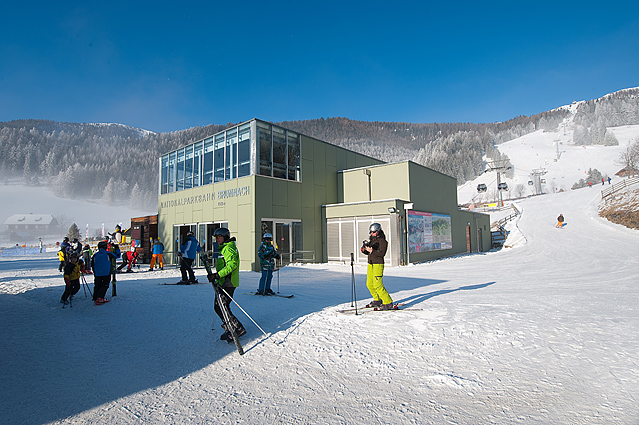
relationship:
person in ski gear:
[355, 214, 408, 260] [360, 235, 404, 314]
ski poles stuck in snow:
[343, 252, 366, 317] [308, 293, 468, 369]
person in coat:
[197, 207, 245, 272] [215, 242, 242, 302]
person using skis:
[250, 224, 280, 275] [243, 279, 308, 309]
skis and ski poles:
[243, 279, 308, 309] [274, 252, 301, 312]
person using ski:
[48, 231, 85, 275] [39, 286, 87, 313]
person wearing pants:
[141, 234, 167, 272] [144, 252, 163, 268]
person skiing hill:
[551, 202, 583, 251] [516, 189, 619, 342]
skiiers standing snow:
[48, 224, 301, 354] [130, 327, 495, 396]